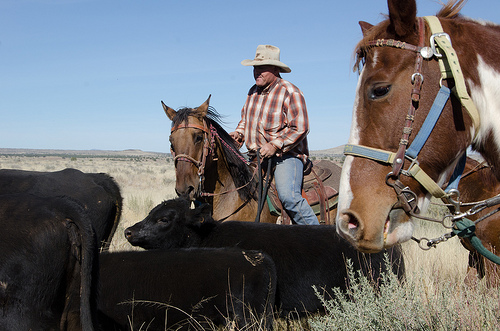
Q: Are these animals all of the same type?
A: No, there are both horses and cows.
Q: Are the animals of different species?
A: Yes, they are horses and cows.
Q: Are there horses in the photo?
A: Yes, there is a horse.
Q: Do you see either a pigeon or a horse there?
A: Yes, there is a horse.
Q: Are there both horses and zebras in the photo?
A: No, there is a horse but no zebras.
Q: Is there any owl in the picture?
A: No, there are no owls.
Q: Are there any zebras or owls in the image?
A: No, there are no owls or zebras.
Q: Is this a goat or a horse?
A: This is a horse.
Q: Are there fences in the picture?
A: No, there are no fences.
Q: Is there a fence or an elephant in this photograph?
A: No, there are no fences or elephants.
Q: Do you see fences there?
A: No, there are no fences.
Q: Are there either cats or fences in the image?
A: No, there are no fences or cats.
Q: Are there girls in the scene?
A: No, there are no girls.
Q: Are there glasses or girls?
A: No, there are no girls or glasses.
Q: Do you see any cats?
A: No, there are no cats.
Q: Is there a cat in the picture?
A: No, there are no cats.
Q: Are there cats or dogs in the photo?
A: No, there are no cats or dogs.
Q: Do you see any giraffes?
A: No, there are no giraffes.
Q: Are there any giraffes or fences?
A: No, there are no giraffes or fences.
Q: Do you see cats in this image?
A: No, there are no cats.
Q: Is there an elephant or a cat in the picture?
A: No, there are no cats or elephants.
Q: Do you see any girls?
A: No, there are no girls.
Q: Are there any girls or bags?
A: No, there are no girls or bags.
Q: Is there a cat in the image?
A: No, there are no cats.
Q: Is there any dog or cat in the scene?
A: No, there are no cats or dogs.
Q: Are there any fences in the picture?
A: No, there are no fences.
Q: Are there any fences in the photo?
A: No, there are no fences.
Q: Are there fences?
A: No, there are no fences.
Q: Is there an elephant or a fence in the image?
A: No, there are no fences or elephants.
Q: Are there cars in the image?
A: No, there are no cars.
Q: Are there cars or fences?
A: No, there are no cars or fences.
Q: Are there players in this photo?
A: No, there are no players.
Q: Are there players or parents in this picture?
A: No, there are no players or parents.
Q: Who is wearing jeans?
A: The cowboy is wearing jeans.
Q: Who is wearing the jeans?
A: The cowboy is wearing jeans.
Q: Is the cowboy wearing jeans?
A: Yes, the cowboy is wearing jeans.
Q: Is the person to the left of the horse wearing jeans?
A: Yes, the cowboy is wearing jeans.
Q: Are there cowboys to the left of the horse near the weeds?
A: Yes, there is a cowboy to the left of the horse.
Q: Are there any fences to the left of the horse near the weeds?
A: No, there is a cowboy to the left of the horse.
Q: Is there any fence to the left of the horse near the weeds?
A: No, there is a cowboy to the left of the horse.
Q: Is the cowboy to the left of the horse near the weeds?
A: Yes, the cowboy is to the left of the horse.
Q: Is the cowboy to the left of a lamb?
A: No, the cowboy is to the left of the horse.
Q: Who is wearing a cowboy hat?
A: The cowboy is wearing a cowboy hat.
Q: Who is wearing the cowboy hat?
A: The cowboy is wearing a cowboy hat.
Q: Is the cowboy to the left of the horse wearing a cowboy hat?
A: Yes, the cowboy is wearing a cowboy hat.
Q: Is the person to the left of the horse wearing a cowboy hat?
A: Yes, the cowboy is wearing a cowboy hat.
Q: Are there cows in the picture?
A: Yes, there are cows.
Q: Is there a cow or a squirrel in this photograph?
A: Yes, there are cows.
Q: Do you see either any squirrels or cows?
A: Yes, there are cows.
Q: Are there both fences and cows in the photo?
A: No, there are cows but no fences.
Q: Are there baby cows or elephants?
A: Yes, there are baby cows.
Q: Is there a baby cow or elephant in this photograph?
A: Yes, there are baby cows.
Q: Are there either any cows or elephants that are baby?
A: Yes, the cows are baby.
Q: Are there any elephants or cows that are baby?
A: Yes, the cows are baby.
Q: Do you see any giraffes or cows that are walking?
A: Yes, the cows are walking.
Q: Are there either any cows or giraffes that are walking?
A: Yes, the cows are walking.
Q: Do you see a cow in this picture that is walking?
A: Yes, there are cows that are walking.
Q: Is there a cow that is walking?
A: Yes, there are cows that are walking.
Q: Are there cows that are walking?
A: Yes, there are cows that are walking.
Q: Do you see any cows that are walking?
A: Yes, there are cows that are walking.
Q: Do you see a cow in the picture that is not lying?
A: Yes, there are cows that are walking .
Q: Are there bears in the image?
A: No, there are no bears.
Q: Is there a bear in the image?
A: No, there are no bears.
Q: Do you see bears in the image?
A: No, there are no bears.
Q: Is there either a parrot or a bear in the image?
A: No, there are no bears or parrots.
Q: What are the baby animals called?
A: The animals are cows.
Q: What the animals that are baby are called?
A: The animals are cows.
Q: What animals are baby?
A: The animals are cows.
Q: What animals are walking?
A: The animals are cows.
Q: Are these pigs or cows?
A: These are cows.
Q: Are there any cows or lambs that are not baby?
A: No, there are cows but they are baby.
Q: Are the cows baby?
A: Yes, the cows are baby.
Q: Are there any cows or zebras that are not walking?
A: No, there are cows but they are walking.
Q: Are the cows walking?
A: Yes, the cows are walking.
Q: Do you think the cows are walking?
A: Yes, the cows are walking.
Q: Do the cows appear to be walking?
A: Yes, the cows are walking.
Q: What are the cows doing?
A: The cows are walking.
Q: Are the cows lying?
A: No, the cows are walking.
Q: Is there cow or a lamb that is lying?
A: No, there are cows but they are walking.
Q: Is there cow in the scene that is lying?
A: No, there are cows but they are walking.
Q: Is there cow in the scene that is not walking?
A: No, there are cows but they are walking.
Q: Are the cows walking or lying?
A: The cows are walking.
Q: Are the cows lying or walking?
A: The cows are walking.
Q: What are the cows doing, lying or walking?
A: The cows are walking.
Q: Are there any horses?
A: Yes, there is a horse.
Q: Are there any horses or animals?
A: Yes, there is a horse.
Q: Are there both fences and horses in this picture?
A: No, there is a horse but no fences.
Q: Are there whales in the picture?
A: No, there are no whales.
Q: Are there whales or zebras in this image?
A: No, there are no whales or zebras.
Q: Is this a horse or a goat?
A: This is a horse.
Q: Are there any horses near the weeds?
A: Yes, there is a horse near the weeds.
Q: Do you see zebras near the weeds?
A: No, there is a horse near the weeds.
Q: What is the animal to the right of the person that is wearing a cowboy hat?
A: The animal is a horse.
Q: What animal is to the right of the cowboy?
A: The animal is a horse.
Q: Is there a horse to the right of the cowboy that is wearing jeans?
A: Yes, there is a horse to the right of the cowboy.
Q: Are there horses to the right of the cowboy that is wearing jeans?
A: Yes, there is a horse to the right of the cowboy.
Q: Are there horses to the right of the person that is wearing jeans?
A: Yes, there is a horse to the right of the cowboy.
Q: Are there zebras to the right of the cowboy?
A: No, there is a horse to the right of the cowboy.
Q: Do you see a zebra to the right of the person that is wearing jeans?
A: No, there is a horse to the right of the cowboy.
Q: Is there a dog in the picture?
A: No, there are no dogs.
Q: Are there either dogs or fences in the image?
A: No, there are no dogs or fences.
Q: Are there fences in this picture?
A: No, there are no fences.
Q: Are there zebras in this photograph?
A: No, there are no zebras.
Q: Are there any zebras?
A: No, there are no zebras.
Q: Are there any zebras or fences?
A: No, there are no zebras or fences.